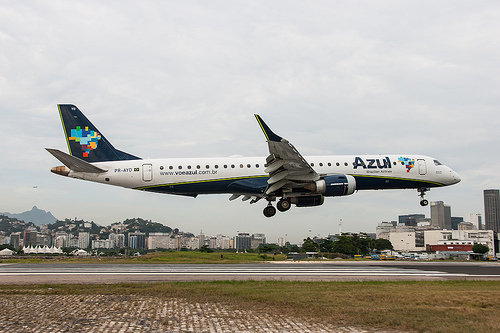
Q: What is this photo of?
A: A plane.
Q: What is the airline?
A: Azul.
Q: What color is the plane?
A: White.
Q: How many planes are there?
A: 1.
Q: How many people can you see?
A: 0.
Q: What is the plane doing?
A: Landing.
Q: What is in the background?
A: A town.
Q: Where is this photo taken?
A: An airport.